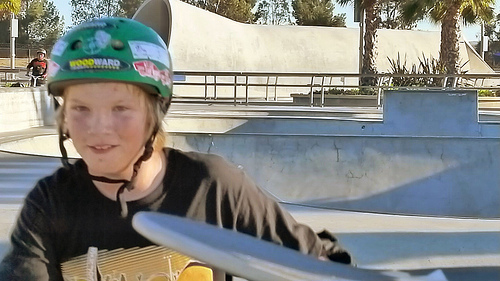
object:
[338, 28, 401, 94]
tree trunk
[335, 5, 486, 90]
foliage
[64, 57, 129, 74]
sticker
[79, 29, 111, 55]
sticker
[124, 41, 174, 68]
sticker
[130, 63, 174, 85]
sticker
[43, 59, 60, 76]
sticker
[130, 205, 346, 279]
skatepark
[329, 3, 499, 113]
trees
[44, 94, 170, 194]
straps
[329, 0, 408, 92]
tree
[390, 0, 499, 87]
tree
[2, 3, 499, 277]
park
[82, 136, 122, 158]
smile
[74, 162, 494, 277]
design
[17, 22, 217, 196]
boy's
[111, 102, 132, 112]
eye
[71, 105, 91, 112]
eye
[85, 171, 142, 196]
strap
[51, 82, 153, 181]
face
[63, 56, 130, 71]
logo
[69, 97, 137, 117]
eyes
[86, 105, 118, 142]
nose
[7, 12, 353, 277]
boy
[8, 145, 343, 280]
shirt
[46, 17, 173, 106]
helmet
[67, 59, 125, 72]
colored logo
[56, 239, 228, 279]
picture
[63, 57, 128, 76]
picture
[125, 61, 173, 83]
picture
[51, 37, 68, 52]
picture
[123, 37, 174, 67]
picture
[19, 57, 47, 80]
shirt